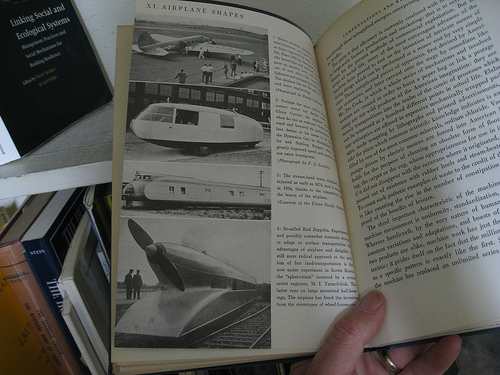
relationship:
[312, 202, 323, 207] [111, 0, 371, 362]
word on page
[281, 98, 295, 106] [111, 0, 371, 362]
word on page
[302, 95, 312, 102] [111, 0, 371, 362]
word on page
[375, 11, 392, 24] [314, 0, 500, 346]
word on page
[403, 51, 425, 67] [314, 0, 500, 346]
word on page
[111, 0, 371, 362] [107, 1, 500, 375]
page in a book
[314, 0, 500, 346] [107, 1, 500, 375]
page in a book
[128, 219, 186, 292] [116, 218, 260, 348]
propeller on a plane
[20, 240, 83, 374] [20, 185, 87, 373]
binder of a book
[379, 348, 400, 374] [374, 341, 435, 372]
ring on a person's finger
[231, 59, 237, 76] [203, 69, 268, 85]
person walking on a sidewalk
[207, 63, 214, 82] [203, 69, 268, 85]
person walking on a sidewalk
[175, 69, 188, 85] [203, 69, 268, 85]
person walking on a sidewalk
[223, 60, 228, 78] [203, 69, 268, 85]
person walking on a sidewalk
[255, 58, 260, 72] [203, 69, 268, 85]
person walking on a sidewalk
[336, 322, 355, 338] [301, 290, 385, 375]
grooves in a person's finger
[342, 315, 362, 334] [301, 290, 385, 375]
grooves in a person's finger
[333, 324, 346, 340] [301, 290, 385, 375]
grooves in a person's finger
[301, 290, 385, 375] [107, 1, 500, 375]
thumb at bottom of a book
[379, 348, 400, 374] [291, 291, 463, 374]
ring on a hand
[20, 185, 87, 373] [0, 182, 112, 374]
book on bottom shelf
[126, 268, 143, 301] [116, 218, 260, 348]
men are standing next to plane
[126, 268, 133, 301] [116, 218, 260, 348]
men are standing next to plane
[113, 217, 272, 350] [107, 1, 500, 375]
bottom picture of open book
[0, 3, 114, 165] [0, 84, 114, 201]
book on top shelf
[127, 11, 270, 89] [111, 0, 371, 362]
picture on page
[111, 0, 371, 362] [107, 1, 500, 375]
page of an open book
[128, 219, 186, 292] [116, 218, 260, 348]
propeller on plane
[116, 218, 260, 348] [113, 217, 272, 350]
plane in bottom picture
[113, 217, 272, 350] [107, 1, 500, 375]
bottom picture in open book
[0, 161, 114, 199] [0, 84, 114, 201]
front of shelf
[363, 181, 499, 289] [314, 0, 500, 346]
paragraph on page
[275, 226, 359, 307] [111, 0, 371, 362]
paragraph on page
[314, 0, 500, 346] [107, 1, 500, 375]
page of an open book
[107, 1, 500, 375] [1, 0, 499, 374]
book in front of shelves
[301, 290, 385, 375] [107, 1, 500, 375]
thumb holding book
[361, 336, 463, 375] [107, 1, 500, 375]
fingers are holding book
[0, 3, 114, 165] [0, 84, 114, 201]
book on shelf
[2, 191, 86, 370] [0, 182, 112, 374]
book on shelf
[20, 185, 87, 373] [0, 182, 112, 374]
book on shelf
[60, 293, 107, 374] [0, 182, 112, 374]
book on shelf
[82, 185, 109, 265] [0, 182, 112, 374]
book on shelf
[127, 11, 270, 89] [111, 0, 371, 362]
photograph on page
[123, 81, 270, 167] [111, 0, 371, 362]
photograph on page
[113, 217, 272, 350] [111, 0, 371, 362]
photograph on page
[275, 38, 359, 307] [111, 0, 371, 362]
text on page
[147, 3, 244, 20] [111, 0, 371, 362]
text on page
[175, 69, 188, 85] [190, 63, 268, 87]
person on a ramp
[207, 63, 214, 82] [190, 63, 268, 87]
person on a ramp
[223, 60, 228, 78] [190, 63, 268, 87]
person on a ramp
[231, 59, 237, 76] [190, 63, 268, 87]
person on a ramp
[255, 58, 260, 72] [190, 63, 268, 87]
person on a ramp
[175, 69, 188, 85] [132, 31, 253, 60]
person looking at airplane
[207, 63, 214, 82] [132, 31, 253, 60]
person looking at airplane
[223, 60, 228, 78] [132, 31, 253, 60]
person looking at airplane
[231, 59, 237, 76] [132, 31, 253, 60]
person looking at airplane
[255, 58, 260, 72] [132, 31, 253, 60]
person looking at airplane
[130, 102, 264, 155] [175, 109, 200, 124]
vehicle has windows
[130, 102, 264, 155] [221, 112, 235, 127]
vehicle has windows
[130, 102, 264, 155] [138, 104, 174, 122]
vehicle has windows